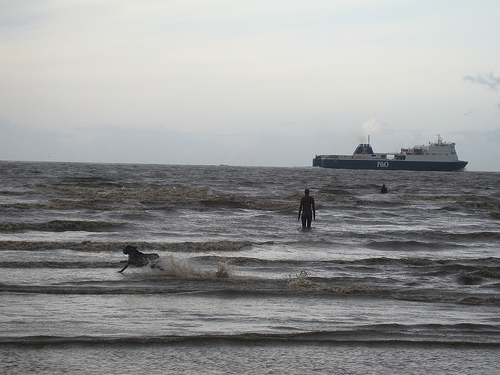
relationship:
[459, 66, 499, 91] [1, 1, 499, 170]
cloud in sky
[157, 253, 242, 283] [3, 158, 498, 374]
waves in water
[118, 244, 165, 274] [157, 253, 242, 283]
dog in waves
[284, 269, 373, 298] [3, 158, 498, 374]
waves in water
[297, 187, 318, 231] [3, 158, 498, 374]
person in water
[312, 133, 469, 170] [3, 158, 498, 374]
ship in water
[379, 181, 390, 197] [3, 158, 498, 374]
person in water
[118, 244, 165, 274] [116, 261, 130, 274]
dog has leg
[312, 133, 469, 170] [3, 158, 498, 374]
ship on water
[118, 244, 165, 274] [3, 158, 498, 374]
dog in water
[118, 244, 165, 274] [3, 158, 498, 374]
dog running in water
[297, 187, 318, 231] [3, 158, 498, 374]
person walking in water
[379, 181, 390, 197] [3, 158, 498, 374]
person walking in water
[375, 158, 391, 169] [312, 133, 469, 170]
text on ship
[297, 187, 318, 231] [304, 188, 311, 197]
person has head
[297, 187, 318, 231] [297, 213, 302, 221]
person has hand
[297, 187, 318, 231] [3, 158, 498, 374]
person standing in water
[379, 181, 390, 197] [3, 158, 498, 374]
person standing in water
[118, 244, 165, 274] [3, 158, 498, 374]
dog walking in water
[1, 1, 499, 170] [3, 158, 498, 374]
sky over water